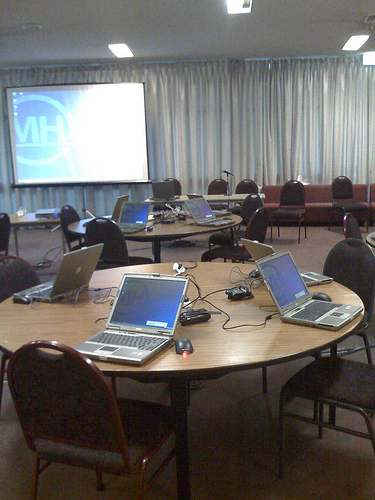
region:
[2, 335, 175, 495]
a padded metal chair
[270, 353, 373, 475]
a padded metal chair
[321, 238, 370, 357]
a padded metal chair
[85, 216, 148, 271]
a padded metal chair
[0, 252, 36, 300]
a padded metal chair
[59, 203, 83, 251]
a padded metal chair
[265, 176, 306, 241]
a padded metal chair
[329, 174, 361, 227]
a padded metal chair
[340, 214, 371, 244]
a padded metal chair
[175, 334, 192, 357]
a wired computer mouse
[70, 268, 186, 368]
an open laptop computer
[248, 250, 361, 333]
an open laptop computer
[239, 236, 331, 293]
an open laptop computer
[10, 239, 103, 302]
an open laptop computer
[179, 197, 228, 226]
an open laptop computer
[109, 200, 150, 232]
an open laptop computer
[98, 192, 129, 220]
an open laptop computer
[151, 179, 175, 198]
an open laptop computer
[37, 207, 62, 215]
a closed laptop computer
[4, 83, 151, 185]
a large projection screen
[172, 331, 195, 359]
the mouse is on the table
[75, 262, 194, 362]
the laptop is open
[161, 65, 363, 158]
the curtain is closed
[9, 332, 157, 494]
the chair is red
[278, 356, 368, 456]
the chair is gray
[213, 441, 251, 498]
the floor is brown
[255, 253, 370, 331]
the laptop is gray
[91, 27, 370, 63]
the lights are on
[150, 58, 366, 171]
the curtains are white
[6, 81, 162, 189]
the screen is up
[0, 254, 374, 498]
the table is round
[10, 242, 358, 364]
the laptops are on the table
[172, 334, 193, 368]
the mouse is black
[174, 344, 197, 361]
the mouse has a red light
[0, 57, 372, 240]
the curtain is white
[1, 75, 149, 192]
the screen is large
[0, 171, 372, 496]
many chairs are in the room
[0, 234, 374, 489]
chairs are around the table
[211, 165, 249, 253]
the microphone is in the front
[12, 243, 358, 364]
the laptops are grey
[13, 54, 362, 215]
a wall of curtains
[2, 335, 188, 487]
an old conference chair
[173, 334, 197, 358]
computer mouse with red light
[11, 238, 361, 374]
a few silver computers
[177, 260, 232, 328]
a few electrical wires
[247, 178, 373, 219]
a long red couch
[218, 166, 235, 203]
a microphone on a stand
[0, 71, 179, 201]
a square projector screen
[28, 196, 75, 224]
a silver projector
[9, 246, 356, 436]
a large round banquet table